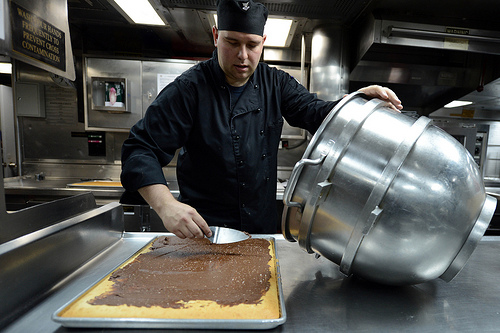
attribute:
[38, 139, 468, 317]
table — steel , metal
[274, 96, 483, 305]
bowl — large, silver, mixing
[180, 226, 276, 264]
spatula — small, silver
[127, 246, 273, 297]
sauce — chocolate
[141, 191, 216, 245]
hand — holding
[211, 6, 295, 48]
hat — black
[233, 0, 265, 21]
pin — silver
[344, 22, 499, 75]
system — silver, black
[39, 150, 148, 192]
dessert — cooling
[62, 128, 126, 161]
object — red, black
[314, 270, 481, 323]
table — steel, metal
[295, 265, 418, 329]
table — metal, steel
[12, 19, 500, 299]
kitchen — industrial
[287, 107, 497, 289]
bowl — large, metal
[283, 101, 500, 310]
bowl — metal, large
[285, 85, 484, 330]
bin — metal, silver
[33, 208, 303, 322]
pan — silver